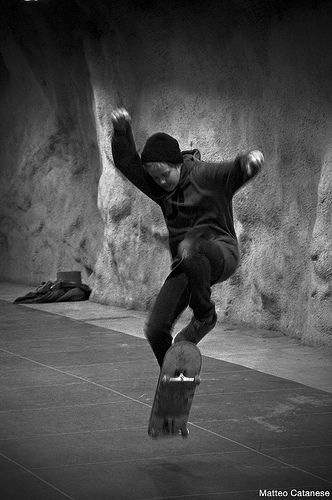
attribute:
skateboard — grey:
[144, 346, 210, 440]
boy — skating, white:
[87, 91, 277, 432]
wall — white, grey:
[8, 33, 331, 316]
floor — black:
[8, 308, 303, 499]